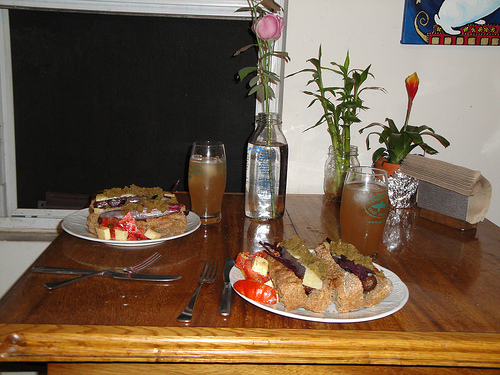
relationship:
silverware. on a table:
[23, 250, 233, 325] [0, 204, 500, 371]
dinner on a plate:
[234, 237, 393, 314] [221, 227, 416, 321]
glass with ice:
[189, 140, 226, 225] [193, 155, 220, 170]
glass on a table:
[334, 165, 391, 263] [0, 204, 500, 371]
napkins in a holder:
[395, 146, 491, 216] [392, 146, 493, 236]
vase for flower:
[219, 103, 317, 231] [251, 14, 284, 40]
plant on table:
[368, 72, 451, 170] [0, 204, 500, 371]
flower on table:
[308, 52, 371, 141] [0, 204, 500, 371]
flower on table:
[251, 14, 284, 40] [0, 204, 500, 371]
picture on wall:
[399, 8, 497, 49] [277, 6, 498, 206]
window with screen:
[7, 4, 257, 219] [13, 6, 262, 218]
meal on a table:
[326, 255, 362, 299] [31, 166, 493, 358]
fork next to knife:
[176, 260, 220, 322] [220, 254, 232, 314]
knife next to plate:
[218, 254, 236, 318] [225, 246, 410, 326]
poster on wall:
[395, 1, 499, 49] [284, 3, 494, 150]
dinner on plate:
[246, 240, 383, 308] [227, 232, 414, 327]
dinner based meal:
[234, 237, 393, 314] [271, 214, 493, 322]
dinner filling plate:
[234, 237, 393, 314] [227, 232, 414, 327]